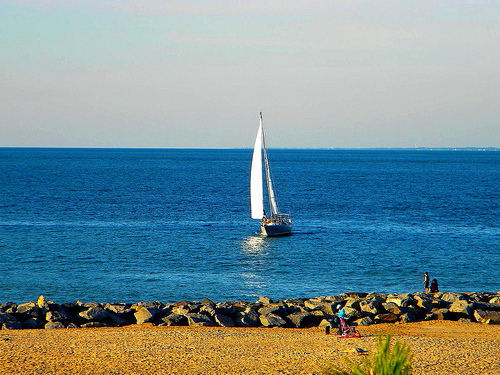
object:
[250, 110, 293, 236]
boat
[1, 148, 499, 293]
water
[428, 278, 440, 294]
people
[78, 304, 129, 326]
rocks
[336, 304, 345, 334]
person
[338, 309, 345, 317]
shirt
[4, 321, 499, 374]
beach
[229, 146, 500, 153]
city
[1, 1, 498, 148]
sky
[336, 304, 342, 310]
hat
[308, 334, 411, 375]
plant